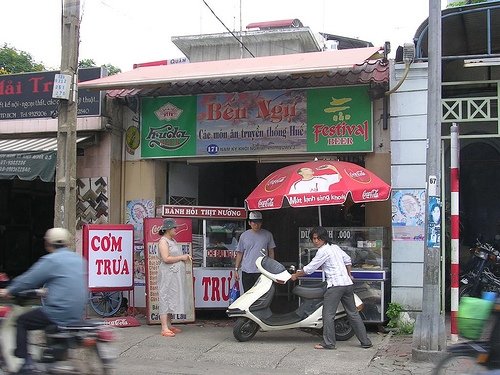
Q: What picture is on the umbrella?
A: A man drinking a soda.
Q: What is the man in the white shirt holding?
A: A moped.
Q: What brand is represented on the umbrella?
A: Coca-Cola.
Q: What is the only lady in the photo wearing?
A: A dress.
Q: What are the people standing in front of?
A: A business.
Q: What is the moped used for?
A: Transportation.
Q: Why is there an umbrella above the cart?
A: To protect from sun and rain.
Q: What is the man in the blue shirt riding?
A: A moped.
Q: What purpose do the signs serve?
A: Advertising.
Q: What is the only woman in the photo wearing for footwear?
A: Sandals.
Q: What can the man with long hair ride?
A: Scooter.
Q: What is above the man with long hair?
A: An umbrella.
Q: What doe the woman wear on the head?
A: A hat.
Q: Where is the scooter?
A: On the sidewalk.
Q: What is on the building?
A: A sign.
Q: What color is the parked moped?
A: White.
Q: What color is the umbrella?
A: Red.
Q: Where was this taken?
A: Street.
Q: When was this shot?
A: Daytime.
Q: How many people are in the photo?
A: 4.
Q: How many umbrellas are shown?
A: 1.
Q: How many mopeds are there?
A: 3.